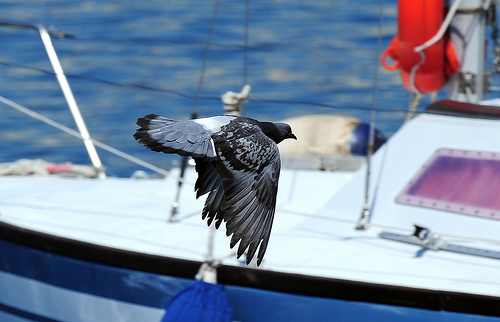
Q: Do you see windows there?
A: Yes, there is a window.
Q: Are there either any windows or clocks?
A: Yes, there is a window.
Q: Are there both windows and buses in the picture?
A: No, there is a window but no buses.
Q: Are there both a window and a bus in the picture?
A: No, there is a window but no buses.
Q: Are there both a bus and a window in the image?
A: No, there is a window but no buses.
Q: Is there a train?
A: No, there are no trains.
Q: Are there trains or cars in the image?
A: No, there are no trains or cars.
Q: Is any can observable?
A: No, there are no cans.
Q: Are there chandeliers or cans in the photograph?
A: No, there are no cans or chandeliers.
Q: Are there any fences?
A: No, there are no fences.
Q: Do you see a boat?
A: Yes, there is a boat.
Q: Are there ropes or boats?
A: Yes, there is a boat.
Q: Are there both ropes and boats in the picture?
A: Yes, there are both a boat and a rope.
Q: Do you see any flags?
A: No, there are no flags.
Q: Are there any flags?
A: No, there are no flags.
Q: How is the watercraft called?
A: The watercraft is a boat.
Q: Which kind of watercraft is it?
A: The watercraft is a boat.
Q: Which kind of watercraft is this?
A: This is a boat.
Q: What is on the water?
A: The boat is on the water.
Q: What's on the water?
A: The boat is on the water.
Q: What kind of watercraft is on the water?
A: The watercraft is a boat.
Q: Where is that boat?
A: The boat is on the water.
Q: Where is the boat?
A: The boat is on the water.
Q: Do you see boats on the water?
A: Yes, there is a boat on the water.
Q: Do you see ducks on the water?
A: No, there is a boat on the water.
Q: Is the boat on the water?
A: Yes, the boat is on the water.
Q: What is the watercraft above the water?
A: The watercraft is a boat.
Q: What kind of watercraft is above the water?
A: The watercraft is a boat.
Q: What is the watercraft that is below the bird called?
A: The watercraft is a boat.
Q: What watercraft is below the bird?
A: The watercraft is a boat.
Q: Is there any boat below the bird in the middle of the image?
A: Yes, there is a boat below the bird.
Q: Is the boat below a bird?
A: Yes, the boat is below a bird.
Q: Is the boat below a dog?
A: No, the boat is below a bird.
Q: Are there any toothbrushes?
A: No, there are no toothbrushes.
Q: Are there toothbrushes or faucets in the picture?
A: No, there are no toothbrushes or faucets.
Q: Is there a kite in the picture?
A: No, there are no kites.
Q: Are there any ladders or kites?
A: No, there are no kites or ladders.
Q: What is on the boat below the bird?
A: The ropes are on the boat.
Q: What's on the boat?
A: The ropes are on the boat.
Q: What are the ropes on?
A: The ropes are on the boat.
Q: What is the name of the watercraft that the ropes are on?
A: The watercraft is a boat.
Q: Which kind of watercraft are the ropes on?
A: The ropes are on the boat.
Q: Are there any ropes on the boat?
A: Yes, there are ropes on the boat.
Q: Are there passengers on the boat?
A: No, there are ropes on the boat.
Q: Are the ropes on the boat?
A: Yes, the ropes are on the boat.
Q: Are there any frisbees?
A: No, there are no frisbees.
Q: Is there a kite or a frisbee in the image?
A: No, there are no frisbees or kites.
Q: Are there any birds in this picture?
A: Yes, there is a bird.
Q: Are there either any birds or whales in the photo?
A: Yes, there is a bird.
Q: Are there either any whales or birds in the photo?
A: Yes, there is a bird.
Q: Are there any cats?
A: No, there are no cats.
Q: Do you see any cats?
A: No, there are no cats.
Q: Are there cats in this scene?
A: No, there are no cats.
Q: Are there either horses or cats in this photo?
A: No, there are no cats or horses.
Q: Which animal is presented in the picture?
A: The animal is a bird.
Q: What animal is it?
A: The animal is a bird.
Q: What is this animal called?
A: This is a bird.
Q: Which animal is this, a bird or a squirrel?
A: This is a bird.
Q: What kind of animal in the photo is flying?
A: The animal is a bird.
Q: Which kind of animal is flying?
A: The animal is a bird.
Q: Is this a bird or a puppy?
A: This is a bird.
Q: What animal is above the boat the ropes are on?
A: The animal is a bird.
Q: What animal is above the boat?
A: The animal is a bird.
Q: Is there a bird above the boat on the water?
A: Yes, there is a bird above the boat.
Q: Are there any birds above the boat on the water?
A: Yes, there is a bird above the boat.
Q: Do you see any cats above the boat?
A: No, there is a bird above the boat.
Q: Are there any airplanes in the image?
A: No, there are no airplanes.